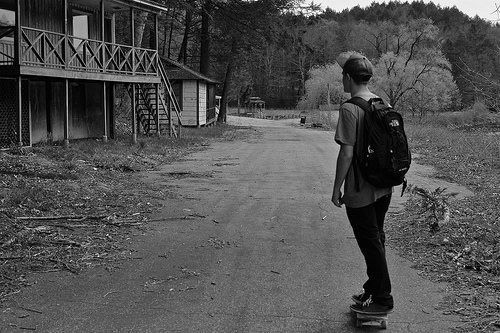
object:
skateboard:
[356, 302, 387, 328]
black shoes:
[349, 298, 393, 314]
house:
[143, 51, 220, 128]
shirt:
[334, 94, 393, 209]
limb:
[11, 202, 118, 233]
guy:
[330, 52, 394, 313]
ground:
[415, 114, 451, 139]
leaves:
[448, 158, 498, 198]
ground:
[13, 107, 498, 331]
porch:
[0, 22, 163, 86]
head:
[335, 51, 373, 92]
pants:
[346, 193, 394, 307]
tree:
[217, 0, 332, 126]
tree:
[226, 66, 256, 116]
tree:
[298, 60, 353, 112]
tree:
[364, 14, 460, 108]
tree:
[283, 13, 343, 98]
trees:
[161, 2, 205, 61]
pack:
[342, 95, 411, 197]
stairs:
[121, 76, 182, 139]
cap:
[340, 48, 374, 79]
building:
[0, 0, 184, 151]